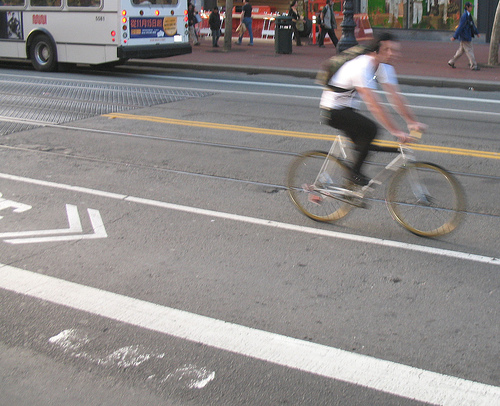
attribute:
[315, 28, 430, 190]
guy — riding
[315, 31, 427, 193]
man — riding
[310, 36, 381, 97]
backpack — camouflauge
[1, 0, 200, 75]
bus — white, backed, stopped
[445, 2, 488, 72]
person — walking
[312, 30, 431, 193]
male — riding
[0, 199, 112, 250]
arrows — white, painted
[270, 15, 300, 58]
can — trash, public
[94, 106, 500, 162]
line — yellow, doubled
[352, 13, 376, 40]
sign — orange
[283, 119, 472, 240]
bicycle — blurry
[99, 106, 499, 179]
stripe — yellow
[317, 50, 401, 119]
shirt — white, plain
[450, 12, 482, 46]
jacket — blue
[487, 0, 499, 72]
trunk — brown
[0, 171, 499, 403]
lane — paved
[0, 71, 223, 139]
grate — metal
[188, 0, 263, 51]
people — loading, walking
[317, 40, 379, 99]
sack — blurry